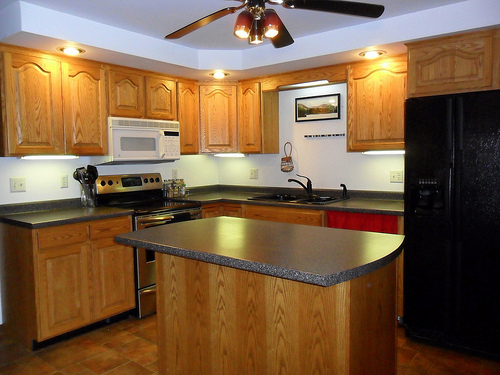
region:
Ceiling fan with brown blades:
[163, 0, 385, 51]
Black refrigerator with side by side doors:
[399, 88, 496, 358]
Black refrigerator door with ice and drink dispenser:
[398, 92, 458, 352]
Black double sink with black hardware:
[245, 173, 358, 205]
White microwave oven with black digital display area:
[88, 117, 181, 165]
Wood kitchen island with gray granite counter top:
[98, 214, 407, 374]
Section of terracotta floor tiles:
[0, 318, 153, 373]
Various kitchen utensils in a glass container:
[72, 163, 99, 210]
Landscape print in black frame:
[293, 91, 341, 122]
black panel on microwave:
[163, 128, 180, 138]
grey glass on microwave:
[121, 139, 160, 147]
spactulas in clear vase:
[72, 165, 100, 185]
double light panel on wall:
[0, 174, 33, 194]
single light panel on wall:
[62, 169, 72, 191]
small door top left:
[105, 72, 145, 113]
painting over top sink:
[290, 91, 343, 128]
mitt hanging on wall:
[278, 138, 295, 175]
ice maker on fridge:
[408, 173, 445, 221]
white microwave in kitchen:
[113, 106, 190, 168]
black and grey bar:
[167, 204, 402, 298]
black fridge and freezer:
[410, 102, 495, 362]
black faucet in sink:
[288, 164, 315, 194]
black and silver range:
[88, 169, 203, 326]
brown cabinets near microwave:
[13, 55, 99, 158]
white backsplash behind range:
[191, 156, 234, 175]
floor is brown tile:
[90, 309, 145, 374]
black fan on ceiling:
[177, 1, 359, 65]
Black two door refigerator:
[399, 93, 499, 353]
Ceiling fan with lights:
[155, 1, 386, 46]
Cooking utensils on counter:
[72, 163, 100, 208]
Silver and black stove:
[93, 175, 200, 220]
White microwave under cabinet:
[107, 116, 180, 162]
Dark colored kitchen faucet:
[286, 171, 315, 199]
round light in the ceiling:
[55, 39, 86, 58]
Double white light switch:
[10, 178, 26, 191]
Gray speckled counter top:
[120, 214, 399, 279]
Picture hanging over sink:
[294, 92, 339, 120]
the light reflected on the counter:
[212, 213, 398, 262]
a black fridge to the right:
[401, 94, 498, 357]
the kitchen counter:
[119, 215, 406, 286]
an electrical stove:
[95, 174, 199, 325]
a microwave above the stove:
[109, 115, 182, 160]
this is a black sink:
[253, 175, 333, 207]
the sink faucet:
[288, 173, 313, 203]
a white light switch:
[11, 176, 26, 193]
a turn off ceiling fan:
[163, 2, 388, 47]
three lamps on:
[64, 46, 383, 80]